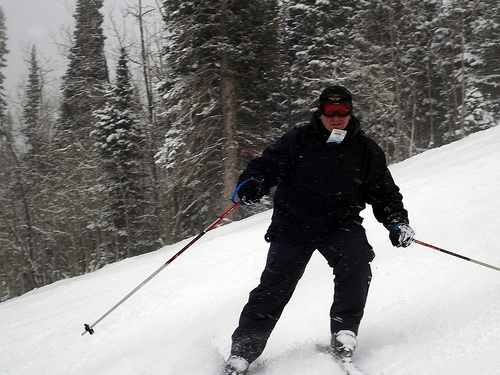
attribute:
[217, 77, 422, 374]
person — skating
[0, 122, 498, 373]
snow — filled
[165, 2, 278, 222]
tree — snow covered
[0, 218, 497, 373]
snow — white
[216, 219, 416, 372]
pant — Black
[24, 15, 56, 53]
sky — hazy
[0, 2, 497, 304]
trees — tall 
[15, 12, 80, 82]
sky — cloudy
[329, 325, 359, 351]
snow — white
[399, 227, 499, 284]
ski pole — red, silver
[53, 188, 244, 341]
ski pole — red, silver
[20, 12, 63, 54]
sky — grey, cold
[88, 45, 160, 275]
tree — covered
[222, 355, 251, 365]
snow — white